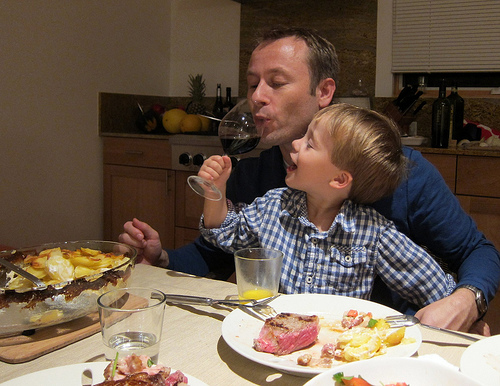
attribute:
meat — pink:
[250, 309, 322, 354]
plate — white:
[222, 286, 428, 371]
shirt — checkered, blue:
[203, 190, 456, 311]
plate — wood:
[1, 285, 152, 360]